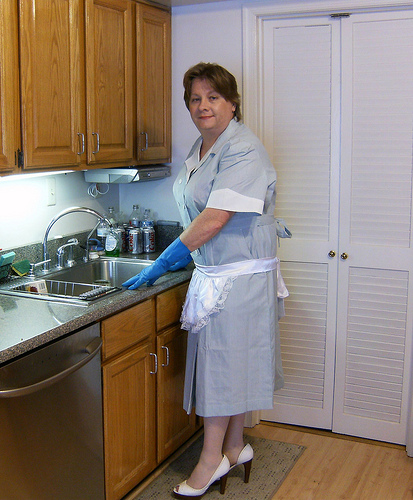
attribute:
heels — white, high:
[176, 446, 253, 494]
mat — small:
[131, 426, 305, 496]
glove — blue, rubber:
[137, 259, 175, 279]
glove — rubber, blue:
[168, 259, 187, 273]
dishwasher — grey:
[25, 332, 159, 499]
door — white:
[264, 13, 389, 232]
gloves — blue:
[83, 232, 225, 313]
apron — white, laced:
[178, 256, 310, 324]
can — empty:
[142, 225, 155, 255]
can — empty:
[127, 227, 142, 256]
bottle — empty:
[90, 206, 110, 246]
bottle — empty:
[129, 201, 140, 225]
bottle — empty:
[140, 206, 151, 227]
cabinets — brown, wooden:
[11, 8, 173, 159]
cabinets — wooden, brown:
[106, 325, 180, 491]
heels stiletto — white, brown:
[173, 438, 251, 498]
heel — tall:
[213, 470, 229, 498]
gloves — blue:
[125, 245, 182, 289]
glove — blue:
[123, 234, 188, 291]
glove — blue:
[166, 251, 190, 271]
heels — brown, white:
[177, 455, 268, 495]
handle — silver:
[140, 347, 160, 379]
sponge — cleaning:
[14, 258, 32, 278]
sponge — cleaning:
[0, 247, 18, 269]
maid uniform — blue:
[176, 136, 283, 354]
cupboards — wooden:
[0, 27, 176, 165]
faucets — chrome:
[13, 195, 121, 288]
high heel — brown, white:
[176, 453, 234, 499]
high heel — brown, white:
[232, 434, 255, 485]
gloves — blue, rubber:
[110, 228, 192, 307]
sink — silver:
[66, 228, 186, 307]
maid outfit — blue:
[169, 125, 272, 484]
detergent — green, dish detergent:
[103, 214, 126, 254]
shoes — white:
[171, 440, 257, 497]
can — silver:
[139, 223, 157, 254]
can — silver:
[128, 225, 144, 254]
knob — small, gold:
[339, 253, 347, 261]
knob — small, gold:
[326, 249, 334, 261]